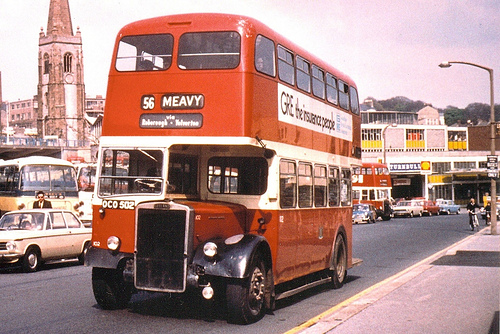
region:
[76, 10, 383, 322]
The bus is a doubledecker.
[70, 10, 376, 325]
The bus is red and white.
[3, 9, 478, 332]
The bus is on the street.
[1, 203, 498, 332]
The street is dry.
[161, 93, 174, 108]
The letter is white.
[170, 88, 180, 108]
The letter is white.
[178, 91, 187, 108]
The letter is white.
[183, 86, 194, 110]
The letter is white.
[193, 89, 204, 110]
The letter is white.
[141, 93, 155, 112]
The number is white.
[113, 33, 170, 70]
glass window on bus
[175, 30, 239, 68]
glass window on bus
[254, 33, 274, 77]
glass window on bus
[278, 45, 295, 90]
glass window on bus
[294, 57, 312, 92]
glass window on bus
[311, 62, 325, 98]
glass window on bus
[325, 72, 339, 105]
glass window on bus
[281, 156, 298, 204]
glass window on bus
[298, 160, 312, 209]
glass window on bus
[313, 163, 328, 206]
glass window on bus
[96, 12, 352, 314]
red double decker bus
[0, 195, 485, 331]
asphalt street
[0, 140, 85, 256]
cars on the the side of the road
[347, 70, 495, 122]
trees in the distance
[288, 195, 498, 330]
sidewalk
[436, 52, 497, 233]
lamp post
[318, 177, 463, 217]
old-fashioned cars lining the streets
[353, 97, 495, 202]
buildings on the side of the street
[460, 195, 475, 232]
person riding a bicycle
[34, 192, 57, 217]
man walking past car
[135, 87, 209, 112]
sign is for bus route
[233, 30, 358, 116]
windows on the bus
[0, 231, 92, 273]
car parked on side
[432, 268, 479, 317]
sidewalk on the right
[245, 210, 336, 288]
red part of bus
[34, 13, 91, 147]
clock tower in the distance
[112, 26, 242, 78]
front windows on bus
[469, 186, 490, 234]
people on the sidewalk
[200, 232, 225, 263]
lights on the bus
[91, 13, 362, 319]
a red and white city bus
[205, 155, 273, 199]
a window on a bus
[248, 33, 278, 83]
a window on a bus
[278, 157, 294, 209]
a window on a bus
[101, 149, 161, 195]
the windshield of a bus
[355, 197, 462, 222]
several cars parked on the side of a city street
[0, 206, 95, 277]
a white car on a city street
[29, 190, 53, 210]
a man wearing a suit and sunglasses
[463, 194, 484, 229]
a person riding a bicycle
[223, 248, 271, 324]
the front wheel of a bus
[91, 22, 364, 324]
A red and white double decker bus.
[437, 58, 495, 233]
A street light.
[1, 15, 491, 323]
Vehicles on the road.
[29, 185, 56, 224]
A man in a suit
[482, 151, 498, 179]
A sign posted on a lightpole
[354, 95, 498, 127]
Green leafy trees.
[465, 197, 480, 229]
man with a bicycle in the street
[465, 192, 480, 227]
the man is wearing a black sweater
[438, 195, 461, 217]
blue car parked in the street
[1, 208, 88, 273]
grey car parked in the street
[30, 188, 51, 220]
the man is wearing a suit